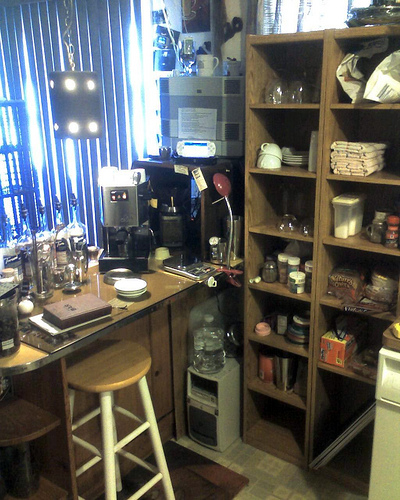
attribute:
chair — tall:
[70, 341, 205, 499]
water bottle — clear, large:
[187, 304, 231, 371]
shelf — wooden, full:
[248, 19, 395, 482]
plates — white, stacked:
[120, 268, 148, 305]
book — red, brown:
[43, 290, 113, 320]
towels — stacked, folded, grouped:
[324, 123, 382, 179]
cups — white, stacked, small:
[238, 144, 292, 177]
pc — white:
[178, 360, 258, 448]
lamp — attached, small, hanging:
[26, 56, 125, 150]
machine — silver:
[77, 162, 157, 271]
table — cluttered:
[12, 261, 195, 351]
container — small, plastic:
[328, 176, 367, 248]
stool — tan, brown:
[54, 342, 167, 498]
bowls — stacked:
[282, 308, 311, 345]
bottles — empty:
[17, 236, 90, 287]